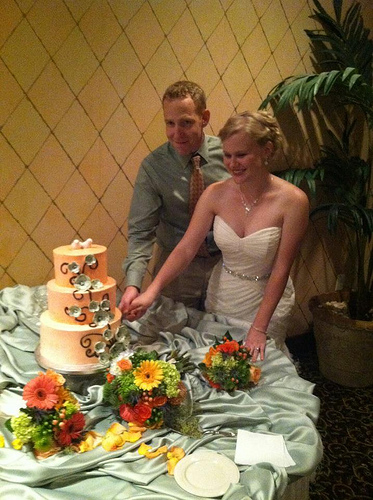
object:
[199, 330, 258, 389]
bouquet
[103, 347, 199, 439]
bouquet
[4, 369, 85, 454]
bouquet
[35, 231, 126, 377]
cake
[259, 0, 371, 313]
plant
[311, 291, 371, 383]
brown pot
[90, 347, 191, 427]
flowers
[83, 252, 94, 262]
flower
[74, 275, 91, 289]
flower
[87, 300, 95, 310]
flower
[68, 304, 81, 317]
flower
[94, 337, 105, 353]
flower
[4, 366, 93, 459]
flower bouquet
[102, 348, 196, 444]
flower bouquet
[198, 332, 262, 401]
flower bouquet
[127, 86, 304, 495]
people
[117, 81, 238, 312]
man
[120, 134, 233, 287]
shirt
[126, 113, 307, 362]
bride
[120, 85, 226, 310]
groom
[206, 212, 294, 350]
dress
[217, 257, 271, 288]
belt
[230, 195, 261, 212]
necklace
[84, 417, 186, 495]
petals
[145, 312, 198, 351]
table cloth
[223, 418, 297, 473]
napkin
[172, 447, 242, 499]
white plate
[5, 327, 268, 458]
bouquets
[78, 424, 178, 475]
rose petals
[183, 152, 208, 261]
tie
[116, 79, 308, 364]
couple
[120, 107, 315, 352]
woman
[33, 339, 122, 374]
plate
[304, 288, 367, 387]
pot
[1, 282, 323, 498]
table